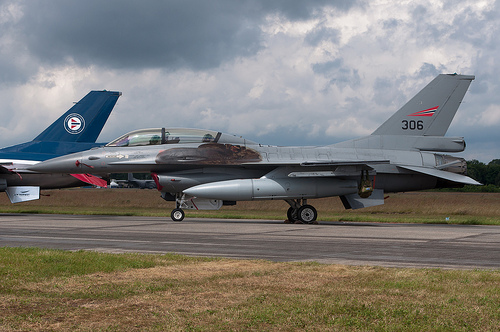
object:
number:
[401, 120, 423, 131]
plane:
[12, 72, 476, 223]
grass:
[0, 251, 499, 331]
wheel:
[170, 208, 185, 222]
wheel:
[298, 204, 318, 224]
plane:
[0, 89, 122, 203]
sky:
[0, 0, 499, 163]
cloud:
[0, 0, 500, 162]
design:
[406, 105, 439, 116]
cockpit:
[106, 128, 259, 146]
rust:
[155, 143, 263, 166]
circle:
[63, 113, 86, 135]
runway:
[1, 210, 499, 274]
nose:
[9, 153, 73, 173]